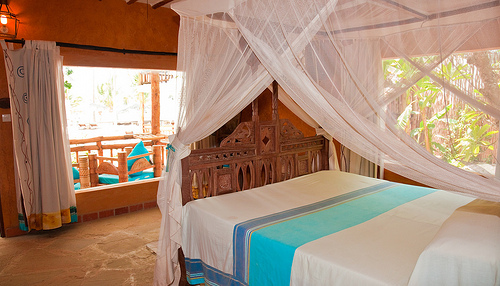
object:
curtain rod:
[0, 38, 177, 56]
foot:
[179, 118, 329, 206]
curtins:
[167, 1, 499, 161]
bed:
[170, 118, 499, 285]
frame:
[185, 259, 203, 285]